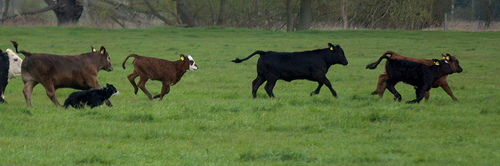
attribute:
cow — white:
[4, 45, 36, 115]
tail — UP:
[229, 47, 266, 65]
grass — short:
[278, 123, 416, 163]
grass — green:
[198, 99, 305, 144]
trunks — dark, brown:
[44, 0, 448, 27]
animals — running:
[11, 15, 477, 122]